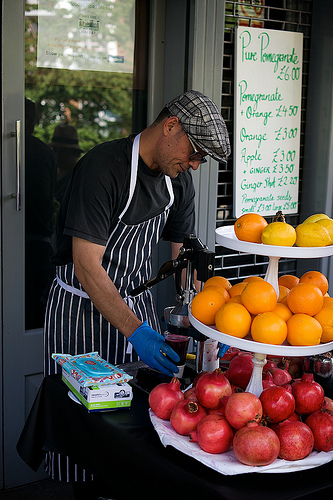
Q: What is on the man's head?
A: A cap.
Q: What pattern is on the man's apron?
A: Stripes.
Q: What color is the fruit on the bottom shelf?
A: Red.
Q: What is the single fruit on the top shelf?
A: An orange.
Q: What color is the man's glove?
A: Blue.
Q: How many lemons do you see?
A: Four.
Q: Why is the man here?
A: To sell fruit.